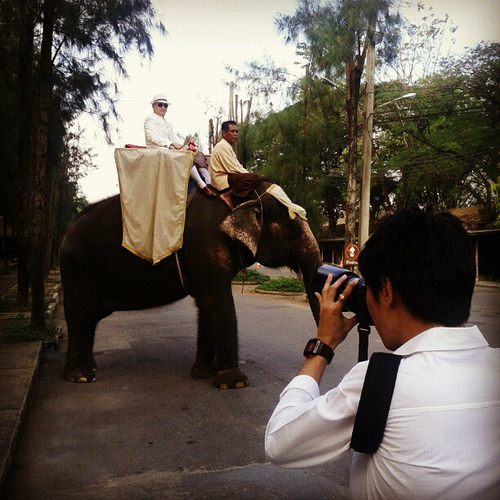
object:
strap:
[358, 325, 371, 361]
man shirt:
[205, 135, 256, 194]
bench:
[107, 146, 209, 174]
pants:
[188, 165, 212, 189]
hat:
[150, 92, 172, 109]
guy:
[144, 92, 215, 197]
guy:
[207, 118, 257, 194]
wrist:
[289, 335, 337, 382]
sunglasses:
[155, 102, 170, 107]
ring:
[336, 293, 346, 301]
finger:
[339, 279, 355, 302]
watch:
[302, 337, 336, 363]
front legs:
[201, 265, 241, 371]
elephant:
[57, 173, 334, 391]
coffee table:
[123, 129, 185, 147]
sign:
[344, 242, 362, 264]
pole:
[351, 2, 380, 272]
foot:
[214, 367, 249, 391]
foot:
[191, 364, 217, 379]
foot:
[63, 366, 97, 381]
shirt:
[265, 323, 500, 499]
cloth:
[109, 145, 202, 262]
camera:
[309, 255, 374, 337]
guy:
[291, 204, 500, 488]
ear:
[217, 195, 264, 258]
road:
[38, 395, 254, 497]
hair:
[220, 119, 239, 131]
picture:
[62, 100, 351, 390]